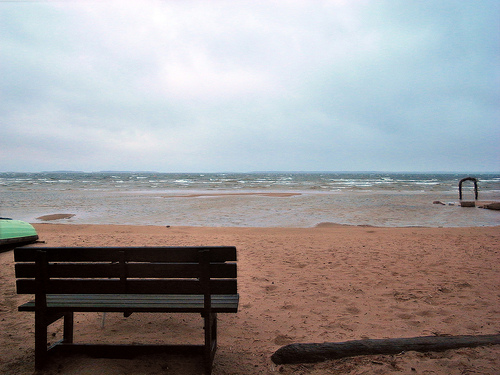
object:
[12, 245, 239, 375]
bench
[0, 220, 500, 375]
beach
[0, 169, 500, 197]
ocean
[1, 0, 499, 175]
sky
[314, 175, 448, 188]
wave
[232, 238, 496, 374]
footprints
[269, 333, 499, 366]
wood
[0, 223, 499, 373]
sand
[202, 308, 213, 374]
leg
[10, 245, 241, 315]
back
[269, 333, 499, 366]
log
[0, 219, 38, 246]
boat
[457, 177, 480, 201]
structure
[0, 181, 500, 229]
water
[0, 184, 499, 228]
far beach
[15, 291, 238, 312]
seat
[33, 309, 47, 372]
left leg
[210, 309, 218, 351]
right leg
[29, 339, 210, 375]
shadow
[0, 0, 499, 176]
clouds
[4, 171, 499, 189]
waves